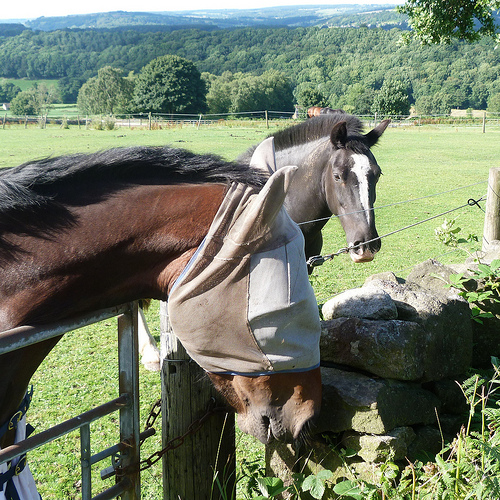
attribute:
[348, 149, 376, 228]
hide is white — black